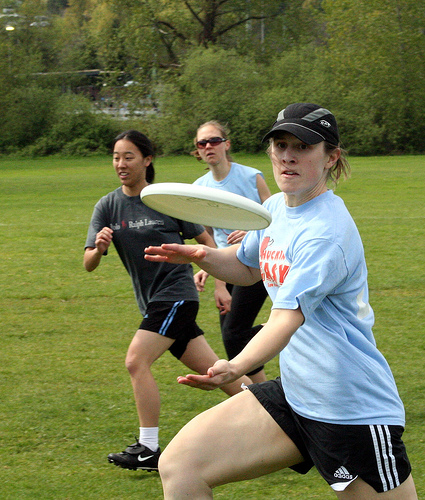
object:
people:
[153, 97, 423, 499]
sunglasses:
[193, 135, 228, 149]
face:
[194, 120, 225, 168]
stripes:
[383, 424, 401, 488]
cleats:
[144, 466, 153, 473]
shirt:
[234, 185, 407, 429]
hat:
[258, 100, 340, 155]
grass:
[0, 156, 424, 499]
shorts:
[136, 300, 206, 363]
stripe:
[159, 299, 180, 334]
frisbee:
[139, 181, 274, 233]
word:
[125, 217, 166, 228]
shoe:
[106, 434, 162, 473]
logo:
[255, 234, 293, 289]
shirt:
[83, 184, 205, 317]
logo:
[136, 451, 155, 462]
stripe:
[369, 421, 390, 492]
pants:
[238, 372, 414, 497]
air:
[21, 168, 65, 257]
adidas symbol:
[330, 463, 357, 481]